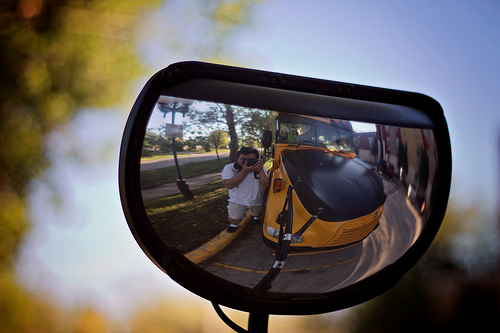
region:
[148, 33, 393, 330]
a mirror that is outside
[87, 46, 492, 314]
a small mirror that is outside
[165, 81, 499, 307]
a mirror with a bus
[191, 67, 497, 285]
a mirror with a yellow bus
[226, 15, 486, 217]
a bus in a mirror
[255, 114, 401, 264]
a yellow bus in the mirror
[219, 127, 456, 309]
a school bus in the mirror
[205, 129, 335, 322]
a man in the mirror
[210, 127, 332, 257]
a mirror wiht a man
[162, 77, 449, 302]
a man in a small mirror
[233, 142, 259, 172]
head of a person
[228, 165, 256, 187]
arm of a person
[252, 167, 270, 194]
arm of a person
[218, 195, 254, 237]
leg of a person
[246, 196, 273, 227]
leg of a person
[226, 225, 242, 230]
feet of a person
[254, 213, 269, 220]
feet of a person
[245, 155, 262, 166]
hand of a person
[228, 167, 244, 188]
an arm of a person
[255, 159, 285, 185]
an arm of a person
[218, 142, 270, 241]
man's reflection in mirror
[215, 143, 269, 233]
adult male in white shirt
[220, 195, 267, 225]
men's khaki cargo shorts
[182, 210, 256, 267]
reflection of yellow curb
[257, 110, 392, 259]
reflection of bus in mirror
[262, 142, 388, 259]
front end of yellow bus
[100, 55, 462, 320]
silver and black mirror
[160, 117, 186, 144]
street sign on pole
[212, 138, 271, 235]
man taking picture near bus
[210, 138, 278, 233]
man with black hair near bus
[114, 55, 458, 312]
man taking picture in mirror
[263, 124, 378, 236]
front of school bus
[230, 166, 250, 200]
whtie shirt on man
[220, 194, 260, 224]
tan shorts on man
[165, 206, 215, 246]
grass growing on median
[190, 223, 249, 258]
yellow concrete edge of median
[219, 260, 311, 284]
yellow lines on concrete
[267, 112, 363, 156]
glass windshield of bus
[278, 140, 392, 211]
black hood of bus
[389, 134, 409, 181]
green trees near building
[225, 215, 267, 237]
Man wearing shoes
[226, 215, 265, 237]
Man is wearing shoes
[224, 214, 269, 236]
Man wearing black shoes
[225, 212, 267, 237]
Man is wearing black shoes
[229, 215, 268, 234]
Man is wearing socks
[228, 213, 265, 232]
Man wearing socks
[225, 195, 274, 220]
Man is wearing shorts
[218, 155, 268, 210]
Man wearing a white shirt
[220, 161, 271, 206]
Man is wearing a white shirt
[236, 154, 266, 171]
Man is holding a black camera